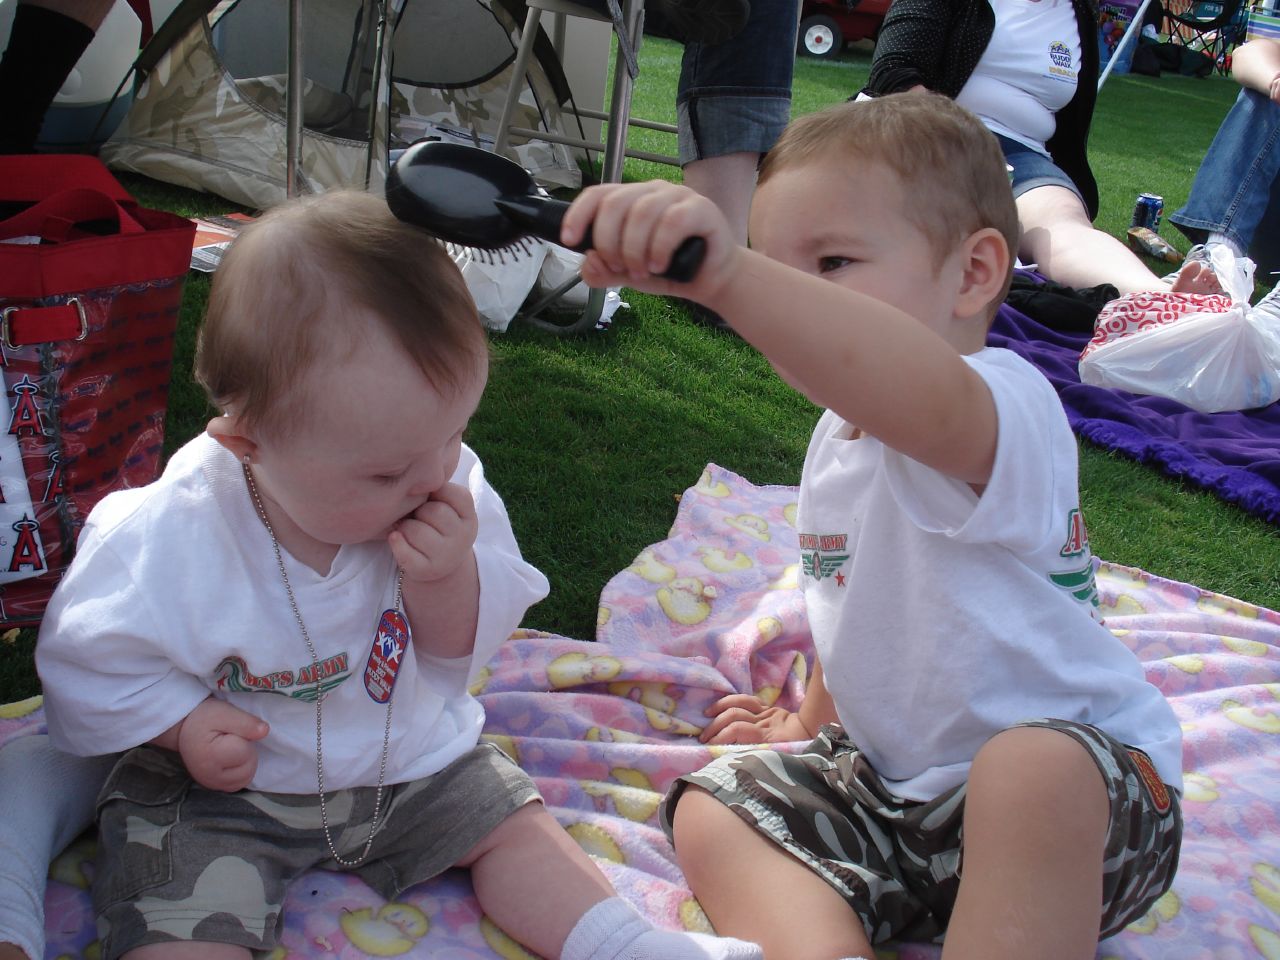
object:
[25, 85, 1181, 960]
children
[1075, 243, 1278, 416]
bag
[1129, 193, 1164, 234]
can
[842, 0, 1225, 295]
people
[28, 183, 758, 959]
baby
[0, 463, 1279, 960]
blanket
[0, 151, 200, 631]
bag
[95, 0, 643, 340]
fence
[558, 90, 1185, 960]
boy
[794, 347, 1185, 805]
shirt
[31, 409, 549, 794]
shirt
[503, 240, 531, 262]
bristle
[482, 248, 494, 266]
bristle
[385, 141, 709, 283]
bristle brush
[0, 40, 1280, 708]
grass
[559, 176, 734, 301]
hand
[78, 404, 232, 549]
back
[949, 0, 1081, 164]
shirt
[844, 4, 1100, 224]
sweater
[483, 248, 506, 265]
bristle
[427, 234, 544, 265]
bristle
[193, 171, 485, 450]
hair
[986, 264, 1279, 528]
blanket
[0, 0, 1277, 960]
ground